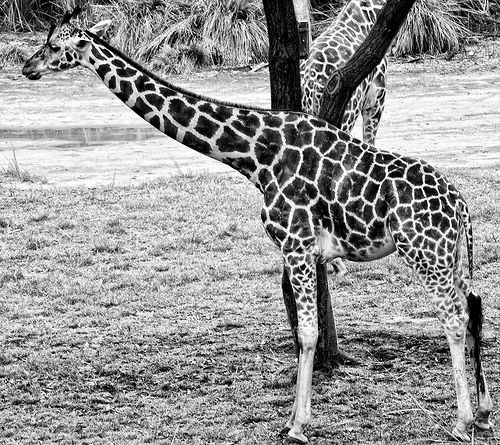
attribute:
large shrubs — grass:
[0, 2, 497, 77]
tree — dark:
[257, 0, 423, 372]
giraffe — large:
[17, 6, 495, 443]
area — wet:
[0, 125, 163, 147]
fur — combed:
[111, 71, 479, 264]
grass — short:
[17, 211, 256, 414]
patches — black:
[371, 106, 378, 117]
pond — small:
[2, 81, 234, 178]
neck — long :
[87, 31, 249, 174]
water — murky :
[1, 122, 171, 157]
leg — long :
[262, 301, 344, 393]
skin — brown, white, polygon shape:
[192, 101, 479, 265]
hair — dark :
[462, 289, 486, 394]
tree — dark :
[262, 1, 402, 372]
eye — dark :
[34, 24, 71, 82]